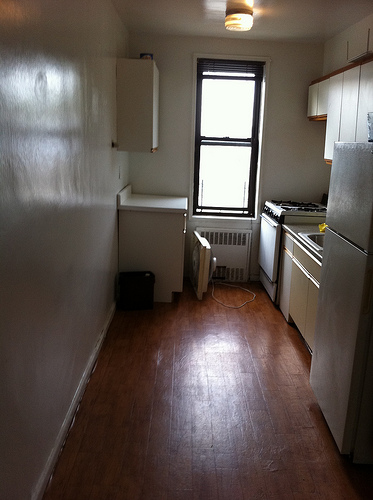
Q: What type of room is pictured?
A: It is a kitchen.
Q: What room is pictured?
A: It is a kitchen.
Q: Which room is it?
A: It is a kitchen.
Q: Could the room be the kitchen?
A: Yes, it is the kitchen.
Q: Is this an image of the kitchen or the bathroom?
A: It is showing the kitchen.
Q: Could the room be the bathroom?
A: No, it is the kitchen.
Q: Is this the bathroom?
A: No, it is the kitchen.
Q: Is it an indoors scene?
A: Yes, it is indoors.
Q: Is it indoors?
A: Yes, it is indoors.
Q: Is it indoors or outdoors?
A: It is indoors.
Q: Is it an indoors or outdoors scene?
A: It is indoors.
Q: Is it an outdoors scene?
A: No, it is indoors.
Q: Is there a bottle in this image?
A: No, there are no bottles.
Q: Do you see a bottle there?
A: No, there are no bottles.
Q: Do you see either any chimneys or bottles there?
A: No, there are no bottles or chimneys.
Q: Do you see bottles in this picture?
A: No, there are no bottles.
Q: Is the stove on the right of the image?
A: Yes, the stove is on the right of the image.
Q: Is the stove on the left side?
A: No, the stove is on the right of the image.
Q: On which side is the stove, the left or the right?
A: The stove is on the right of the image.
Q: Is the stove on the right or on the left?
A: The stove is on the right of the image.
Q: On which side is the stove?
A: The stove is on the right of the image.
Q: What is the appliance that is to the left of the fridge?
A: The appliance is a stove.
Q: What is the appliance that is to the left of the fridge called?
A: The appliance is a stove.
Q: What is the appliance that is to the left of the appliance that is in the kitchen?
A: The appliance is a stove.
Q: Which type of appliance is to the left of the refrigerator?
A: The appliance is a stove.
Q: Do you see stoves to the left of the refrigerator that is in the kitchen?
A: Yes, there is a stove to the left of the fridge.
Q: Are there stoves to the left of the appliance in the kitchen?
A: Yes, there is a stove to the left of the fridge.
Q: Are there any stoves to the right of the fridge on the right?
A: No, the stove is to the left of the freezer.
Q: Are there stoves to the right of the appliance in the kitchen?
A: No, the stove is to the left of the freezer.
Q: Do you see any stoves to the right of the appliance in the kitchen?
A: No, the stove is to the left of the freezer.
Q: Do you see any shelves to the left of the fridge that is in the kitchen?
A: No, there is a stove to the left of the fridge.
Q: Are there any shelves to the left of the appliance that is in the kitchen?
A: No, there is a stove to the left of the fridge.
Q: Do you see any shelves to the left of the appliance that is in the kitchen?
A: No, there is a stove to the left of the fridge.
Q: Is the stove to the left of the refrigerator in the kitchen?
A: Yes, the stove is to the left of the refrigerator.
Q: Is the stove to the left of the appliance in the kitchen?
A: Yes, the stove is to the left of the refrigerator.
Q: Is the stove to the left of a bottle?
A: No, the stove is to the left of the refrigerator.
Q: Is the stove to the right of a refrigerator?
A: No, the stove is to the left of a refrigerator.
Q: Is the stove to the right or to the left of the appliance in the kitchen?
A: The stove is to the left of the freezer.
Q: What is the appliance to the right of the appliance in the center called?
A: The appliance is a stove.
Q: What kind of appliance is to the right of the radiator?
A: The appliance is a stove.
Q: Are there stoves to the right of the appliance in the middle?
A: Yes, there is a stove to the right of the radiator.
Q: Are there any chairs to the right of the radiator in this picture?
A: No, there is a stove to the right of the radiator.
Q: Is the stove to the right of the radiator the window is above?
A: Yes, the stove is to the right of the radiator.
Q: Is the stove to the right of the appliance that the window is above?
A: Yes, the stove is to the right of the radiator.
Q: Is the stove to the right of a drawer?
A: No, the stove is to the right of the radiator.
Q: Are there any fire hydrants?
A: No, there are no fire hydrants.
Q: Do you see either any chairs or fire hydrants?
A: No, there are no fire hydrants or chairs.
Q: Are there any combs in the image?
A: No, there are no combs.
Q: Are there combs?
A: No, there are no combs.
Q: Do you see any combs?
A: No, there are no combs.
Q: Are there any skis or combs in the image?
A: No, there are no combs or skis.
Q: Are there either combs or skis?
A: No, there are no combs or skis.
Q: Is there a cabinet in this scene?
A: Yes, there is a cabinet.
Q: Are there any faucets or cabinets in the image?
A: Yes, there is a cabinet.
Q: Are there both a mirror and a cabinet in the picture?
A: No, there is a cabinet but no mirrors.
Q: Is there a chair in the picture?
A: No, there are no chairs.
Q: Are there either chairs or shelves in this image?
A: No, there are no chairs or shelves.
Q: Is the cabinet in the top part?
A: Yes, the cabinet is in the top of the image.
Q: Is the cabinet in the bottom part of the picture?
A: No, the cabinet is in the top of the image.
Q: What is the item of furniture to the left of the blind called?
A: The piece of furniture is a cabinet.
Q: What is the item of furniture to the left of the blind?
A: The piece of furniture is a cabinet.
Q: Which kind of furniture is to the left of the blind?
A: The piece of furniture is a cabinet.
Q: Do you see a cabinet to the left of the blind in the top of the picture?
A: Yes, there is a cabinet to the left of the blind.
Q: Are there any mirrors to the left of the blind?
A: No, there is a cabinet to the left of the blind.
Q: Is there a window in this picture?
A: Yes, there is a window.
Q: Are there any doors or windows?
A: Yes, there is a window.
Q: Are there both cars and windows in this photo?
A: No, there is a window but no cars.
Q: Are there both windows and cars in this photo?
A: No, there is a window but no cars.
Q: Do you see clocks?
A: No, there are no clocks.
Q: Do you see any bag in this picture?
A: No, there are no bags.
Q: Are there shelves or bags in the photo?
A: No, there are no bags or shelves.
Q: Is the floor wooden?
A: Yes, the floor is wooden.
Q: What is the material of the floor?
A: The floor is made of wood.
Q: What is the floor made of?
A: The floor is made of wood.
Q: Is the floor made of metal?
A: No, the floor is made of wood.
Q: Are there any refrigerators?
A: Yes, there is a refrigerator.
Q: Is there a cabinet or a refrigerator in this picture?
A: Yes, there is a refrigerator.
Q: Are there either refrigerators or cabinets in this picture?
A: Yes, there is a refrigerator.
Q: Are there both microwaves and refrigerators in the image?
A: No, there is a refrigerator but no microwaves.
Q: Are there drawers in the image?
A: No, there are no drawers.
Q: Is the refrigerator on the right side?
A: Yes, the refrigerator is on the right of the image.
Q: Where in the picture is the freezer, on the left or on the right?
A: The freezer is on the right of the image.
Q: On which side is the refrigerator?
A: The refrigerator is on the right of the image.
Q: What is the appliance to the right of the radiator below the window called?
A: The appliance is a refrigerator.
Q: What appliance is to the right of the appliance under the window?
A: The appliance is a refrigerator.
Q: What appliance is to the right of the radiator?
A: The appliance is a refrigerator.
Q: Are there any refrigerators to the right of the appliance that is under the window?
A: Yes, there is a refrigerator to the right of the radiator.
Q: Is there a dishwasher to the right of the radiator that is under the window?
A: No, there is a refrigerator to the right of the radiator.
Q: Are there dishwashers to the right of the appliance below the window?
A: No, there is a refrigerator to the right of the radiator.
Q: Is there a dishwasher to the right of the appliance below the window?
A: No, there is a refrigerator to the right of the radiator.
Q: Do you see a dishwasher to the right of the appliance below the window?
A: No, there is a refrigerator to the right of the radiator.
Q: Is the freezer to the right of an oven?
A: No, the freezer is to the right of the radiator.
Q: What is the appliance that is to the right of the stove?
A: The appliance is a refrigerator.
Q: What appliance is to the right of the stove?
A: The appliance is a refrigerator.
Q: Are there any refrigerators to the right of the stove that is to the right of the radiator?
A: Yes, there is a refrigerator to the right of the stove.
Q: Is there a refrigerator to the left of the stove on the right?
A: No, the refrigerator is to the right of the stove.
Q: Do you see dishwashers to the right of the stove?
A: No, there is a refrigerator to the right of the stove.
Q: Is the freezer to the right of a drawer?
A: No, the freezer is to the right of the stove.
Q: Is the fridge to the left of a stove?
A: No, the fridge is to the right of a stove.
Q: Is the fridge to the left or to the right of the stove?
A: The fridge is to the right of the stove.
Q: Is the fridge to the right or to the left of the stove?
A: The fridge is to the right of the stove.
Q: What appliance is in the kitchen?
A: The appliance is a refrigerator.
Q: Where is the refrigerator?
A: The refrigerator is in the kitchen.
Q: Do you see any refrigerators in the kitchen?
A: Yes, there is a refrigerator in the kitchen.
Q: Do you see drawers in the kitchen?
A: No, there is a refrigerator in the kitchen.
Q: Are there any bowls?
A: No, there are no bowls.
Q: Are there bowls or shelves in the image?
A: No, there are no bowls or shelves.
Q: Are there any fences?
A: No, there are no fences.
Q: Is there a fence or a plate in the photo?
A: No, there are no fences or plates.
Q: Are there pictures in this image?
A: No, there are no pictures.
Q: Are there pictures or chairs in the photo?
A: No, there are no pictures or chairs.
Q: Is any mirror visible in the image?
A: No, there are no mirrors.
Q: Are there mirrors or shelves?
A: No, there are no mirrors or shelves.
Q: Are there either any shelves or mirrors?
A: No, there are no mirrors or shelves.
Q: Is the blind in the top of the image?
A: Yes, the blind is in the top of the image.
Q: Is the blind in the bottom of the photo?
A: No, the blind is in the top of the image.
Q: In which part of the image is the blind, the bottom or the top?
A: The blind is in the top of the image.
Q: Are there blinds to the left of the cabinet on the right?
A: Yes, there is a blind to the left of the cabinet.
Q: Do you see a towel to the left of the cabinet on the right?
A: No, there is a blind to the left of the cabinet.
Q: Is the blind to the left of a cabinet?
A: Yes, the blind is to the left of a cabinet.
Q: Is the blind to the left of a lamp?
A: No, the blind is to the left of a cabinet.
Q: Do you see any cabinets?
A: Yes, there is a cabinet.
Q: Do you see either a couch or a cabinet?
A: Yes, there is a cabinet.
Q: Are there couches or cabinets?
A: Yes, there is a cabinet.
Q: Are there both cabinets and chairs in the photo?
A: No, there is a cabinet but no chairs.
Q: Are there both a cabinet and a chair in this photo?
A: No, there is a cabinet but no chairs.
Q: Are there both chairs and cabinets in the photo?
A: No, there is a cabinet but no chairs.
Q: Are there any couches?
A: No, there are no couches.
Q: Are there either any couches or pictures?
A: No, there are no couches or pictures.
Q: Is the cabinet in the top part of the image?
A: Yes, the cabinet is in the top of the image.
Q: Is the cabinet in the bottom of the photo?
A: No, the cabinet is in the top of the image.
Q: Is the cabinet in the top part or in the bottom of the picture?
A: The cabinet is in the top of the image.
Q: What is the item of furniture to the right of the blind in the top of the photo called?
A: The piece of furniture is a cabinet.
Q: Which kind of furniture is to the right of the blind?
A: The piece of furniture is a cabinet.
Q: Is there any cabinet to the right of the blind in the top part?
A: Yes, there is a cabinet to the right of the blind.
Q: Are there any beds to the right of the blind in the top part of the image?
A: No, there is a cabinet to the right of the blind.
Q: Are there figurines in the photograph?
A: No, there are no figurines.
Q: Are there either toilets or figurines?
A: No, there are no figurines or toilets.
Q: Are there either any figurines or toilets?
A: No, there are no figurines or toilets.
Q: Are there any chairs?
A: No, there are no chairs.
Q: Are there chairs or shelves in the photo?
A: No, there are no chairs or shelves.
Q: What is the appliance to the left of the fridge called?
A: The appliance is a radiator.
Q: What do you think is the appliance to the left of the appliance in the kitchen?
A: The appliance is a radiator.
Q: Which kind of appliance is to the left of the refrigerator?
A: The appliance is a radiator.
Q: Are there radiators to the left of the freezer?
A: Yes, there is a radiator to the left of the freezer.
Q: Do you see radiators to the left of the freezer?
A: Yes, there is a radiator to the left of the freezer.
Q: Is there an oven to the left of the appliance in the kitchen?
A: No, there is a radiator to the left of the freezer.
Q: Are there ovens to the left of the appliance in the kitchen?
A: No, there is a radiator to the left of the freezer.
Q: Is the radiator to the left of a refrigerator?
A: Yes, the radiator is to the left of a refrigerator.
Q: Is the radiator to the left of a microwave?
A: No, the radiator is to the left of a refrigerator.